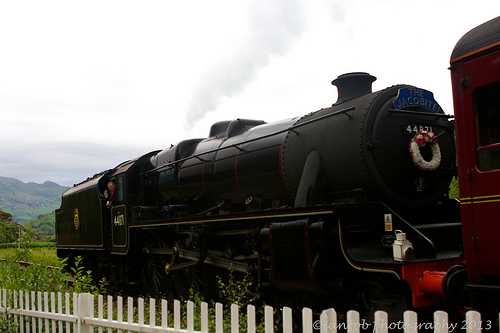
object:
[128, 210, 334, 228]
line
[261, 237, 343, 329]
wheel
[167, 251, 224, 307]
wheel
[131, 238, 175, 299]
wheel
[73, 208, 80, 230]
sign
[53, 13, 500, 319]
train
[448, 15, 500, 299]
train carriage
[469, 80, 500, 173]
window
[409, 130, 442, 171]
wreath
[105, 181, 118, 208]
man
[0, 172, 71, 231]
mountain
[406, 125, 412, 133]
numbers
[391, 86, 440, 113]
poster letterhead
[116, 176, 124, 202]
window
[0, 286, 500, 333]
fence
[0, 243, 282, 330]
grass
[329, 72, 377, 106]
chimney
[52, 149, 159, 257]
cabin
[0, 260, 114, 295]
tracks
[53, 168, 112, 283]
back